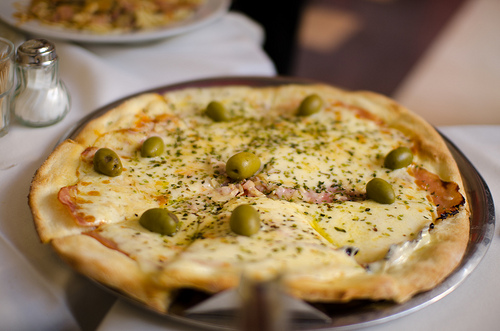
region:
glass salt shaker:
[9, 29, 71, 133]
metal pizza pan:
[455, 133, 497, 320]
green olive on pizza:
[221, 135, 261, 186]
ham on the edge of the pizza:
[416, 132, 458, 237]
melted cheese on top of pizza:
[261, 111, 373, 248]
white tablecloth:
[62, 40, 272, 90]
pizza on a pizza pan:
[30, 76, 487, 326]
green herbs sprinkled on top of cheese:
[260, 112, 337, 175]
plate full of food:
[8, 0, 230, 44]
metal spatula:
[181, 269, 337, 325]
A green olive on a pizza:
[221, 146, 269, 184]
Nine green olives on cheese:
[90, 85, 431, 238]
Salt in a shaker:
[0, 73, 75, 134]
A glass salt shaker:
[5, 15, 75, 135]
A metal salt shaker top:
[5, 35, 75, 75]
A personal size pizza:
[25, 66, 465, 318]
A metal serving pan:
[420, 126, 492, 316]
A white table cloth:
[62, 5, 267, 145]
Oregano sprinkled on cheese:
[256, 120, 368, 202]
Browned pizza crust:
[17, 139, 105, 267]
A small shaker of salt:
[8, 41, 74, 127]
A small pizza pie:
[21, 76, 461, 311]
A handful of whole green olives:
[90, 95, 410, 235]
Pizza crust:
[47, 232, 167, 312]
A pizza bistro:
[0, 0, 495, 325]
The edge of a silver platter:
[385, 121, 495, 326]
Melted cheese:
[302, 203, 438, 254]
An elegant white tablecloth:
[56, 17, 278, 137]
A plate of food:
[2, 0, 232, 40]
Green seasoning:
[229, 115, 381, 188]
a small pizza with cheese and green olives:
[39, 81, 476, 306]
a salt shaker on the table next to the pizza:
[8, 39, 83, 132]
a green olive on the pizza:
[138, 206, 190, 241]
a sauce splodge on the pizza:
[399, 153, 469, 234]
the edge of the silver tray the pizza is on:
[443, 136, 496, 301]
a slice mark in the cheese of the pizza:
[282, 186, 367, 287]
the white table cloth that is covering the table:
[75, 49, 135, 97]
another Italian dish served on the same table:
[11, 3, 241, 49]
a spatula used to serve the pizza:
[184, 261, 347, 325]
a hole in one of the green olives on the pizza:
[228, 155, 245, 185]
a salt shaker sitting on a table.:
[10, 38, 70, 128]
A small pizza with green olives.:
[27, 73, 496, 329]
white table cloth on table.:
[170, 39, 248, 63]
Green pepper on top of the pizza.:
[224, 193, 266, 243]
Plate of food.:
[1, 1, 236, 46]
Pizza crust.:
[27, 138, 87, 244]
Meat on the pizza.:
[54, 180, 85, 227]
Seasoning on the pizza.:
[252, 115, 322, 152]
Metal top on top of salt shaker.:
[16, 34, 57, 66]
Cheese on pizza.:
[327, 204, 386, 238]